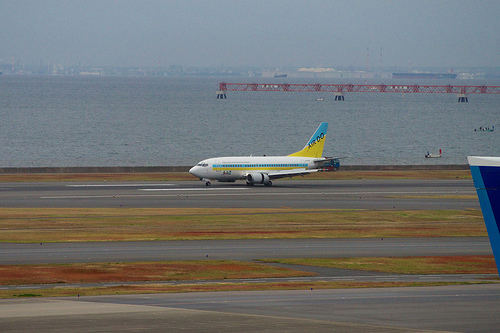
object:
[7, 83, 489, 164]
ocean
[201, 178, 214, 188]
tire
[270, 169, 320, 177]
wing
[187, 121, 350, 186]
airplane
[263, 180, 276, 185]
wheel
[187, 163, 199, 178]
nose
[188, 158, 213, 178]
cockpit area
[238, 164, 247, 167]
passenger window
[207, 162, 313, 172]
stripes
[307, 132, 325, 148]
word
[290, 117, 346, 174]
tail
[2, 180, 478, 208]
airport runway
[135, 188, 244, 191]
lines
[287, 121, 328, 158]
tail fin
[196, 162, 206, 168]
cockpit window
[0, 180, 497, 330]
airplane runway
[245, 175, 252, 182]
propeller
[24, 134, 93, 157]
ripples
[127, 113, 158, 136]
wave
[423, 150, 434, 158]
things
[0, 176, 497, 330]
airplane runways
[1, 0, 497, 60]
sky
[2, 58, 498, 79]
city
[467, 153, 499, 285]
tail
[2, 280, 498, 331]
runway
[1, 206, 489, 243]
grass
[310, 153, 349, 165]
tail wing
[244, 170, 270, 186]
engine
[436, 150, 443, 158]
bouy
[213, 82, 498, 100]
structure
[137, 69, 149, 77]
buildings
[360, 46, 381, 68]
pillar